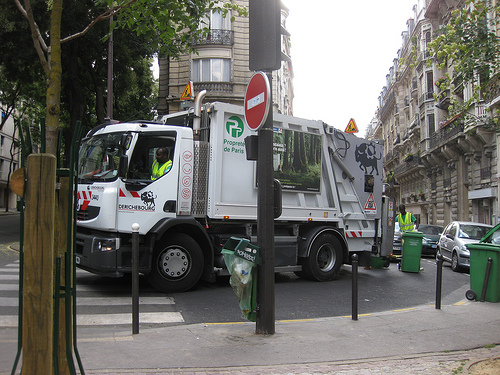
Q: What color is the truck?
A: White.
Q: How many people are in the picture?
A: 2.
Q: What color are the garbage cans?
A: Green.